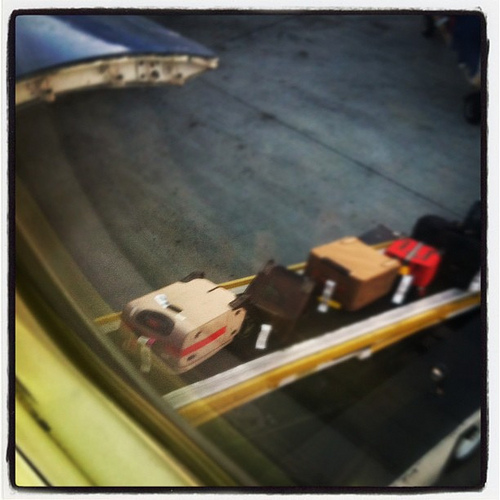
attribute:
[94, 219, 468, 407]
conveyer belt — black, white, yellow, silver, luggage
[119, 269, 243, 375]
suitcase — top, beige, tan, wheeled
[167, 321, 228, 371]
line — red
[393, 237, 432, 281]
bag — red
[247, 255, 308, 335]
bag — brown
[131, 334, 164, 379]
tag — white, destination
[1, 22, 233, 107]
door — up, open, raised, blue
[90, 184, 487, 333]
luggage — red, tan, solid black, huge, solid brown, silver, big, solid, black, nondescript, brown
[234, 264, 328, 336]
suitcase — black, brown, wheeled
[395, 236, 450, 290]
suitcase — red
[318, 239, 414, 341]
suitcase — brown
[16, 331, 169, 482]
metal — yellow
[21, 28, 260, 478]
airplane — view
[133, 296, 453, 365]
tags — white, labeling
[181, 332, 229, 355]
trim — red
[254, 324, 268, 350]
tag — destination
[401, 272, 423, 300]
tag — destination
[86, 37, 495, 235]
pavement — gray, tarmac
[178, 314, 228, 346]
stripe — red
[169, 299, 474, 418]
stripe — yellow